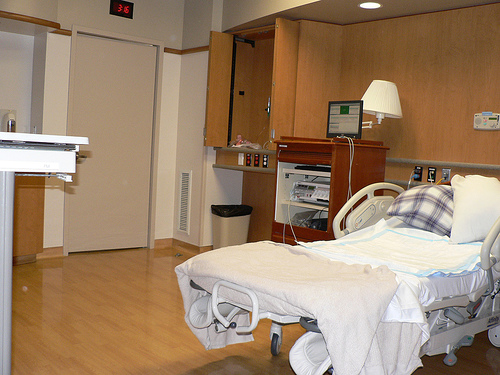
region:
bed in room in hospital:
[6, 3, 498, 369]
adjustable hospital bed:
[176, 181, 499, 373]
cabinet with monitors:
[268, 133, 390, 240]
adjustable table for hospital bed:
[2, 125, 93, 372]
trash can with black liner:
[210, 197, 254, 251]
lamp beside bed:
[348, 72, 403, 136]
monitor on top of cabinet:
[323, 95, 363, 140]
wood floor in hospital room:
[26, 245, 201, 374]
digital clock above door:
[105, 3, 141, 22]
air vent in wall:
[173, 164, 196, 234]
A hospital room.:
[10, 6, 492, 361]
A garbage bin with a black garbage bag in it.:
[205, 195, 255, 255]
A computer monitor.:
[315, 90, 365, 150]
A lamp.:
[355, 65, 410, 140]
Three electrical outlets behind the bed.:
[400, 145, 460, 186]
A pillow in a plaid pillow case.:
[385, 176, 455, 236]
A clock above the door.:
[100, 0, 140, 25]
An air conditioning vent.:
[157, 160, 197, 240]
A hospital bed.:
[170, 161, 495, 361]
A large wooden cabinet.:
[191, 20, 296, 153]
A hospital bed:
[163, 93, 473, 354]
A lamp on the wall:
[268, 84, 468, 101]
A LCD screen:
[326, 73, 364, 136]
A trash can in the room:
[199, 193, 304, 254]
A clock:
[95, 3, 146, 15]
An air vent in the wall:
[173, 164, 187, 245]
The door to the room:
[72, 46, 191, 247]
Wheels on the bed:
[267, 325, 302, 370]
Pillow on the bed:
[386, 172, 483, 260]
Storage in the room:
[187, 56, 378, 256]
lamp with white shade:
[357, 75, 408, 126]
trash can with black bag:
[207, 198, 256, 252]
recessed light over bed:
[352, 0, 386, 12]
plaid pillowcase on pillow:
[391, 183, 453, 232]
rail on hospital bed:
[334, 180, 406, 237]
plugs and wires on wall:
[410, 162, 456, 186]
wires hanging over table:
[341, 139, 358, 193]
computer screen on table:
[320, 97, 365, 144]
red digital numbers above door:
[106, 2, 136, 20]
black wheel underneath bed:
[260, 329, 289, 360]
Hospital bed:
[170, 183, 446, 368]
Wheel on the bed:
[261, 325, 286, 350]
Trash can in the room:
[194, 203, 317, 260]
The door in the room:
[68, 150, 183, 301]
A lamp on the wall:
[366, 85, 413, 127]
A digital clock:
[103, 0, 150, 42]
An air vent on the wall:
[172, 146, 264, 303]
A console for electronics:
[256, 115, 443, 320]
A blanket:
[211, 228, 403, 350]